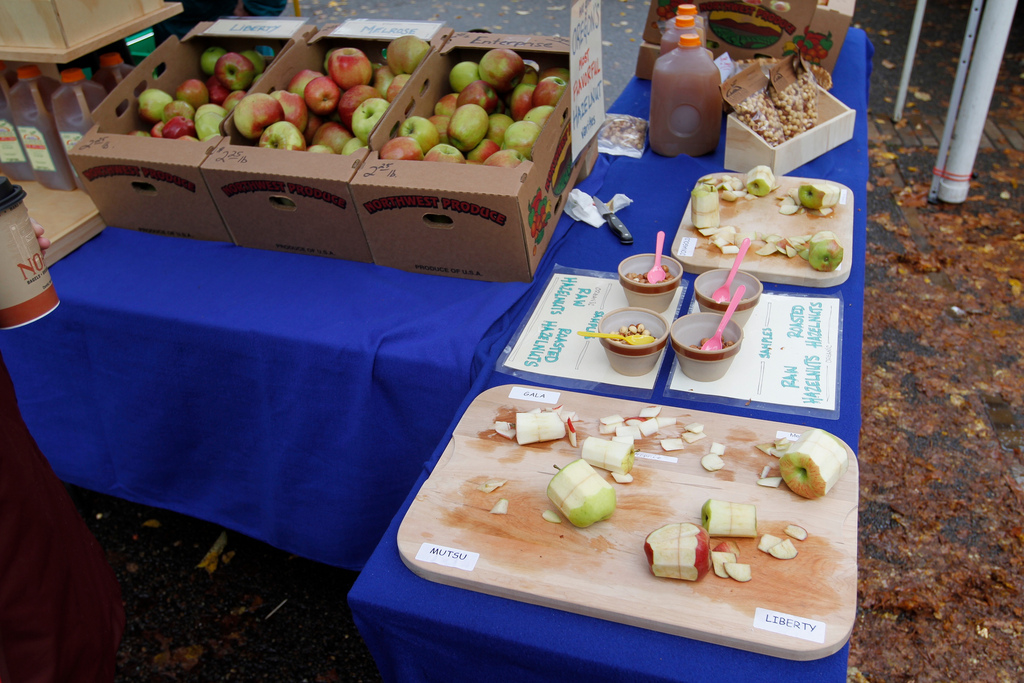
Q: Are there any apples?
A: Yes, there is an apple.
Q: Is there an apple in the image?
A: Yes, there is an apple.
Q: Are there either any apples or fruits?
A: Yes, there is an apple.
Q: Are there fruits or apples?
A: Yes, there is an apple.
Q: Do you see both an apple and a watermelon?
A: No, there is an apple but no watermelons.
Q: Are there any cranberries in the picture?
A: No, there are no cranberries.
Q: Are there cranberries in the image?
A: No, there are no cranberries.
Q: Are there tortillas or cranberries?
A: No, there are no cranberries or tortillas.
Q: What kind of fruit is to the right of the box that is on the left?
A: The fruit is an apple.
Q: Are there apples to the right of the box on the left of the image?
A: Yes, there is an apple to the right of the box.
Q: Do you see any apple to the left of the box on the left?
A: No, the apple is to the right of the box.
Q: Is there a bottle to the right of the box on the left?
A: No, there is an apple to the right of the box.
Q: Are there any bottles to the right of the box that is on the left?
A: No, there is an apple to the right of the box.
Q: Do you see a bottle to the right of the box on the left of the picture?
A: No, there is an apple to the right of the box.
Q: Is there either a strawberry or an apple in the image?
A: Yes, there are apples.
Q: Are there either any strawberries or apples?
A: Yes, there are apples.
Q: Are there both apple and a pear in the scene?
A: No, there are apples but no pears.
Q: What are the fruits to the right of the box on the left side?
A: The fruits are apples.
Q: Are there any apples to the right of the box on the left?
A: Yes, there are apples to the right of the box.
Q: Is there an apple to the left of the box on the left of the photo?
A: No, the apples are to the right of the box.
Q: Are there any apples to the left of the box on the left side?
A: No, the apples are to the right of the box.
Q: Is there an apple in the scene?
A: Yes, there are apples.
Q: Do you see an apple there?
A: Yes, there are apples.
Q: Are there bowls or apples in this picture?
A: Yes, there are apples.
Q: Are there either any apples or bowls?
A: Yes, there are apples.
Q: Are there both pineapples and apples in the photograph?
A: No, there are apples but no pineapples.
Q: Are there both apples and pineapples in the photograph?
A: No, there are apples but no pineapples.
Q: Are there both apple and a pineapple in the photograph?
A: No, there are apples but no pineapples.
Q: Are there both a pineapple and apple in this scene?
A: No, there are apples but no pineapples.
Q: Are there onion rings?
A: No, there are no onion rings.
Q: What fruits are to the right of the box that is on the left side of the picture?
A: The fruits are apples.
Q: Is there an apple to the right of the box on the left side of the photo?
A: Yes, there are apples to the right of the box.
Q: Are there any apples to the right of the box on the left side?
A: Yes, there are apples to the right of the box.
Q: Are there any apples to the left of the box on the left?
A: No, the apples are to the right of the box.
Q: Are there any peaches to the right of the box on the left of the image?
A: No, there are apples to the right of the box.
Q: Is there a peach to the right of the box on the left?
A: No, there are apples to the right of the box.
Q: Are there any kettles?
A: No, there are no kettles.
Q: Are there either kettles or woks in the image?
A: No, there are no kettles or woks.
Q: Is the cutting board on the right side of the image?
A: Yes, the cutting board is on the right of the image.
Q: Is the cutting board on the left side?
A: No, the cutting board is on the right of the image.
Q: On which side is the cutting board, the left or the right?
A: The cutting board is on the right of the image.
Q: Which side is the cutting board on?
A: The cutting board is on the right of the image.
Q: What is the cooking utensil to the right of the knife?
A: The cooking utensil is a cutting board.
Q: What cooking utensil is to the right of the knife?
A: The cooking utensil is a cutting board.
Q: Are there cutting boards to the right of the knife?
A: Yes, there is a cutting board to the right of the knife.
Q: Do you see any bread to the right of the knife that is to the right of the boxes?
A: No, there is a cutting board to the right of the knife.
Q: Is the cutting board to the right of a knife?
A: Yes, the cutting board is to the right of a knife.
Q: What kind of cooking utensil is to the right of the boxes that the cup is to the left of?
A: The cooking utensil is a cutting board.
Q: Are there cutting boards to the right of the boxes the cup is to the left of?
A: Yes, there is a cutting board to the right of the boxes.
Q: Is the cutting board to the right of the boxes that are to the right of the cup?
A: Yes, the cutting board is to the right of the boxes.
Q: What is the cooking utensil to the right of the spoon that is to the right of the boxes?
A: The cooking utensil is a cutting board.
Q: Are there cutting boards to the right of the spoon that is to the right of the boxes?
A: Yes, there is a cutting board to the right of the spoon.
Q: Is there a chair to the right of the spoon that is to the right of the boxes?
A: No, there is a cutting board to the right of the spoon.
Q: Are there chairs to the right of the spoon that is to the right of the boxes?
A: No, there is a cutting board to the right of the spoon.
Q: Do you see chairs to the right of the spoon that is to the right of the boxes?
A: No, there is a cutting board to the right of the spoon.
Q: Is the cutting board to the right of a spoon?
A: Yes, the cutting board is to the right of a spoon.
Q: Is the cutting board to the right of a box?
A: Yes, the cutting board is to the right of a box.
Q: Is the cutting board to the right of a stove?
A: No, the cutting board is to the right of a box.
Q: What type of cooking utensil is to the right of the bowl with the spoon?
A: The cooking utensil is a cutting board.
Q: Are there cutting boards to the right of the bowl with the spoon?
A: Yes, there is a cutting board to the right of the bowl.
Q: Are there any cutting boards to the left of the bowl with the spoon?
A: No, the cutting board is to the right of the bowl.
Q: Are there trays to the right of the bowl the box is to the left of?
A: No, there is a cutting board to the right of the bowl.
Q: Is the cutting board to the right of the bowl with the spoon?
A: Yes, the cutting board is to the right of the bowl.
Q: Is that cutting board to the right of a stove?
A: No, the cutting board is to the right of the bowl.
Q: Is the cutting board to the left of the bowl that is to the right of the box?
A: No, the cutting board is to the right of the bowl.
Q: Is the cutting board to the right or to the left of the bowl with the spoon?
A: The cutting board is to the right of the bowl.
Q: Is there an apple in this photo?
A: Yes, there is an apple.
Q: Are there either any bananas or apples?
A: Yes, there is an apple.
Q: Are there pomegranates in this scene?
A: No, there are no pomegranates.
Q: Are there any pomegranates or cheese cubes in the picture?
A: No, there are no pomegranates or cheese cubes.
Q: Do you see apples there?
A: Yes, there are apples.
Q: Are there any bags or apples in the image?
A: Yes, there are apples.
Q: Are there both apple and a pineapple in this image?
A: No, there are apples but no pineapples.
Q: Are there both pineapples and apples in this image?
A: No, there are apples but no pineapples.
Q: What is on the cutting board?
A: The apples are on the cutting board.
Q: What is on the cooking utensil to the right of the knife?
A: The apples are on the cutting board.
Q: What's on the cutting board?
A: The apples are on the cutting board.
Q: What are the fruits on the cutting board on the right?
A: The fruits are apples.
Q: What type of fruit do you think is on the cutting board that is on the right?
A: The fruits are apples.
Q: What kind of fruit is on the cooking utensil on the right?
A: The fruits are apples.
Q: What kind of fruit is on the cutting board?
A: The fruits are apples.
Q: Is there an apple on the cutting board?
A: Yes, there are apples on the cutting board.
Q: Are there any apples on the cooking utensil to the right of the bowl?
A: Yes, there are apples on the cutting board.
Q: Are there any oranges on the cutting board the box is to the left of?
A: No, there are apples on the cutting board.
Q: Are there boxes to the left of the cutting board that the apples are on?
A: Yes, there are boxes to the left of the cutting board.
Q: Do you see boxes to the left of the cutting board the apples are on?
A: Yes, there are boxes to the left of the cutting board.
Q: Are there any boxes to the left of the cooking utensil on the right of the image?
A: Yes, there are boxes to the left of the cutting board.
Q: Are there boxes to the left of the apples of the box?
A: Yes, there are boxes to the left of the apples.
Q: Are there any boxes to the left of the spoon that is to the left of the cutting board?
A: Yes, there are boxes to the left of the spoon.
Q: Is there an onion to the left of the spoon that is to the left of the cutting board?
A: No, there are boxes to the left of the spoon.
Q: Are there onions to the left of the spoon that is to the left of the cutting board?
A: No, there are boxes to the left of the spoon.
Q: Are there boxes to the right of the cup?
A: Yes, there are boxes to the right of the cup.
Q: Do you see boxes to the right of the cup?
A: Yes, there are boxes to the right of the cup.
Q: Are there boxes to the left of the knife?
A: Yes, there are boxes to the left of the knife.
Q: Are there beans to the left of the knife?
A: No, there are boxes to the left of the knife.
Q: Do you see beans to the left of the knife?
A: No, there are boxes to the left of the knife.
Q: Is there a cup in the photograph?
A: Yes, there is a cup.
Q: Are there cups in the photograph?
A: Yes, there is a cup.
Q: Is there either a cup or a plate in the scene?
A: Yes, there is a cup.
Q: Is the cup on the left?
A: Yes, the cup is on the left of the image.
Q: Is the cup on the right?
A: No, the cup is on the left of the image.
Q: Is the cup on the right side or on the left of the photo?
A: The cup is on the left of the image.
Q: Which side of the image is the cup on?
A: The cup is on the left of the image.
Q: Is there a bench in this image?
A: No, there are no benches.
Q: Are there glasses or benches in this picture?
A: No, there are no benches or glasses.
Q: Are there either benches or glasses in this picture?
A: No, there are no benches or glasses.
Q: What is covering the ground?
A: The leaves are covering the ground.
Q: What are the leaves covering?
A: The leaves are covering the ground.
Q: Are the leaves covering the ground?
A: Yes, the leaves are covering the ground.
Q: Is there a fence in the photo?
A: No, there are no fences.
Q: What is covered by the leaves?
A: The ground is covered by the leaves.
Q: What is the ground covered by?
A: The ground is covered by the leaves.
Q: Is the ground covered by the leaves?
A: Yes, the ground is covered by the leaves.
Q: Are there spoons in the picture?
A: Yes, there is a spoon.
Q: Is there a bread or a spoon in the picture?
A: Yes, there is a spoon.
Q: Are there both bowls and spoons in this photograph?
A: Yes, there are both a spoon and a bowl.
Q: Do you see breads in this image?
A: No, there are no breads.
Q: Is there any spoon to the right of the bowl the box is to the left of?
A: Yes, there is a spoon to the right of the bowl.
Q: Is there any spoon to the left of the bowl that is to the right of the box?
A: No, the spoon is to the right of the bowl.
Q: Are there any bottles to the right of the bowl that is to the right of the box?
A: No, there is a spoon to the right of the bowl.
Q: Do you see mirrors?
A: No, there are no mirrors.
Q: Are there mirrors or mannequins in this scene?
A: No, there are no mirrors or mannequins.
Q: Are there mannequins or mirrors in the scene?
A: No, there are no mirrors or mannequins.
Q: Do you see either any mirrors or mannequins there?
A: No, there are no mirrors or mannequins.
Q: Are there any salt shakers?
A: No, there are no salt shakers.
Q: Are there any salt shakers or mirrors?
A: No, there are no salt shakers or mirrors.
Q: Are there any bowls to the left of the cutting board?
A: Yes, there is a bowl to the left of the cutting board.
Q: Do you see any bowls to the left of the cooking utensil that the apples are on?
A: Yes, there is a bowl to the left of the cutting board.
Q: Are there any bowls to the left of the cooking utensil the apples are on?
A: Yes, there is a bowl to the left of the cutting board.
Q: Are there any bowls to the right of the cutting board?
A: No, the bowl is to the left of the cutting board.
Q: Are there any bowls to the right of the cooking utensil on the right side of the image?
A: No, the bowl is to the left of the cutting board.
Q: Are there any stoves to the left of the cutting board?
A: No, there is a bowl to the left of the cutting board.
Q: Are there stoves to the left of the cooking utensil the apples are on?
A: No, there is a bowl to the left of the cutting board.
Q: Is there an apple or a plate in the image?
A: Yes, there is an apple.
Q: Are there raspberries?
A: No, there are no raspberries.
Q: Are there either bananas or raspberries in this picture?
A: No, there are no raspberries or bananas.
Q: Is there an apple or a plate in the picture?
A: Yes, there are apples.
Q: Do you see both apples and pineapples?
A: No, there are apples but no pineapples.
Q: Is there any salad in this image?
A: No, there is no salad.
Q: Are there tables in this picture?
A: Yes, there is a table.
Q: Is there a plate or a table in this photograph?
A: Yes, there is a table.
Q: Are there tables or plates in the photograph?
A: Yes, there is a table.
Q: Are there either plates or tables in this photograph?
A: Yes, there is a table.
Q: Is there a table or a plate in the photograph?
A: Yes, there is a table.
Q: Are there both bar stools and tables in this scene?
A: No, there is a table but no bar stools.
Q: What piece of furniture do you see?
A: The piece of furniture is a table.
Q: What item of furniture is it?
A: The piece of furniture is a table.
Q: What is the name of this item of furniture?
A: This is a table.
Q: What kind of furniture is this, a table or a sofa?
A: This is a table.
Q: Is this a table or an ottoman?
A: This is a table.